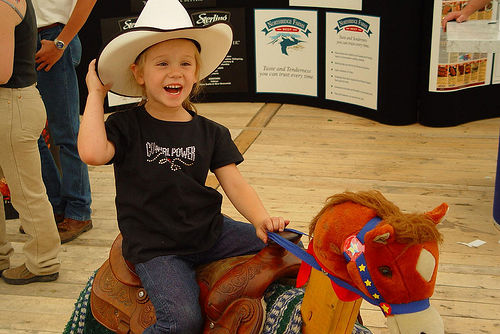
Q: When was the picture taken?
A: Daytime.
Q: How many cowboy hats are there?
A: One.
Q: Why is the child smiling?
A: They are having fun.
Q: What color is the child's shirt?
A: Black.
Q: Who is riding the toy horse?
A: The child.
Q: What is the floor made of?
A: Wood.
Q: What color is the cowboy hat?
A: White.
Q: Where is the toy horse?
A: Beneath the child.